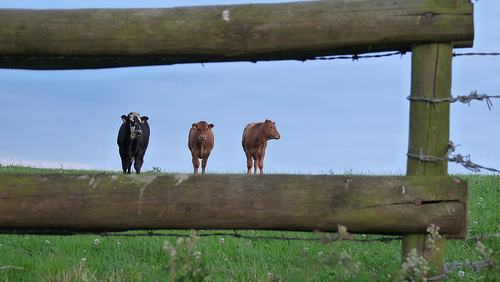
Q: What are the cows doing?
A: Standing in a field.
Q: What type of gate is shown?
A: Wooden and barbed wire.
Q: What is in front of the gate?
A: Flower buds.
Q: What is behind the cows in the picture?
A: Blue sky.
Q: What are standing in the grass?
A: Cows.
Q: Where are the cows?
A: In a fenced field.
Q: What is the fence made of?
A: Wood and metal wires.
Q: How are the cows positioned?
A: Lined up sideways.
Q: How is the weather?
A: Sunny, with blue sky.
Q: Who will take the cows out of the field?
A: The farmer who owns the cows.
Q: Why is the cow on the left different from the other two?
A: Because it is the only black cow.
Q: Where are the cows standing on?
A: On green grass.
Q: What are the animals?
A: Cows.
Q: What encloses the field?
A: Fence.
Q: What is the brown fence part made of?
A: Wood.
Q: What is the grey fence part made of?
A: Metal wire.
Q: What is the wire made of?
A: Metal.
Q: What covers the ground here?
A: Grass.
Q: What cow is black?
A: The one on the left.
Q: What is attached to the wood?
A: Barbed wire.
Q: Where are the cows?
A: In a field.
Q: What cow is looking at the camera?
A: The one in the middle.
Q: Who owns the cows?
A: A farmer.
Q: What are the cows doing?
A: Standing around.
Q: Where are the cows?
A: Green field.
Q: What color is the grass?
A: Green.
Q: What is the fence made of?
A: Wood.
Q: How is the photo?
A: Clear.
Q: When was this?
A: Daytime.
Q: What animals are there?
A: Cows.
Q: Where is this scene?
A: Farm.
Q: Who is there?
A: No one.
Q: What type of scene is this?
A: Outdoor.